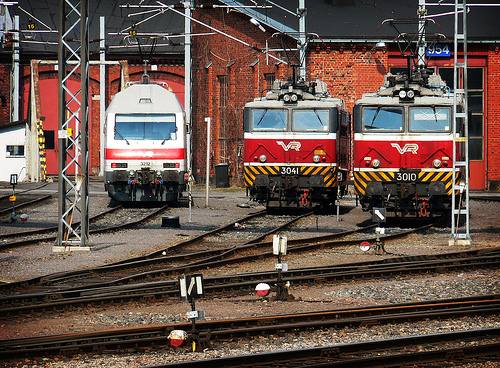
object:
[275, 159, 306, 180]
number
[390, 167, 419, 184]
number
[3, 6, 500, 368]
yard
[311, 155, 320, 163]
lights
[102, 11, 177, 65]
wires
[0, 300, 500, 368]
tracks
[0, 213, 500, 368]
ground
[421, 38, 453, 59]
numbers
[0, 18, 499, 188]
wall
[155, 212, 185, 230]
box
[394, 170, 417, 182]
white number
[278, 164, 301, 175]
white number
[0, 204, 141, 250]
train tracks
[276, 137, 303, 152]
white letters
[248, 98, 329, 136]
windshield wipers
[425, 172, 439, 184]
stripes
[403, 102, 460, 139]
windows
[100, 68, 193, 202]
train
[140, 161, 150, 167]
black numbers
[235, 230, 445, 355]
gravel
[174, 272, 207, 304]
signals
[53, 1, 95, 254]
metal pole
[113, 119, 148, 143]
window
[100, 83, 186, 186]
front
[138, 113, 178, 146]
window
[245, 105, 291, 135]
window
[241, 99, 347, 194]
front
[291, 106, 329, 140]
window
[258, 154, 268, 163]
headlight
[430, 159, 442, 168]
headlight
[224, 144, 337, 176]
frame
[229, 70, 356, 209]
engine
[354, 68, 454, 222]
engine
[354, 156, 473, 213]
frame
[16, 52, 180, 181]
door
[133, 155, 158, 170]
numbers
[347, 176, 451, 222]
trolley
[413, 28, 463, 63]
sign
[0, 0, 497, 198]
building